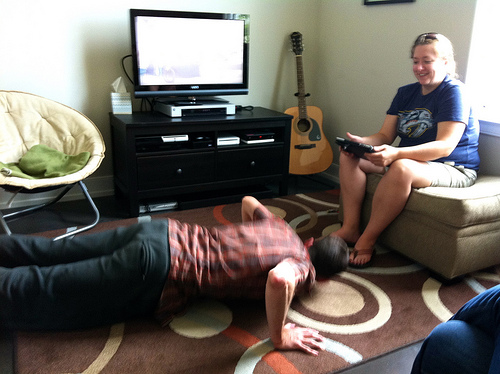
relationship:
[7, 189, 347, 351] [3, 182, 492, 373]
man on floor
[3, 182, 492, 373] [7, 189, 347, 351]
floor below man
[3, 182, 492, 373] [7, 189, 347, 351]
floor under man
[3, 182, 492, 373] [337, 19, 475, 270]
floor below woman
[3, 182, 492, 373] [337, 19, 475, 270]
floor under woman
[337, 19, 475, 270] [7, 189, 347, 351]
woman near man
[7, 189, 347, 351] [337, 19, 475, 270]
man near woman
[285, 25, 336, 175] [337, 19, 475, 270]
guitar near woman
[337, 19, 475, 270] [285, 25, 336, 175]
woman near guitar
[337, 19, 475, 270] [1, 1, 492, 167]
woman near wall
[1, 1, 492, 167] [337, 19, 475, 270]
wall near woman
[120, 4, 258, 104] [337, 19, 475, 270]
tv near woman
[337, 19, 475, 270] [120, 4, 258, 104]
woman near tv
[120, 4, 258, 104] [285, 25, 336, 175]
tv near guitar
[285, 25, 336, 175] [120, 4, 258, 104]
guitar near tv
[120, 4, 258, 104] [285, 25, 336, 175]
tv beside guitar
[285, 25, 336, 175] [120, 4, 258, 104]
guitar beside tv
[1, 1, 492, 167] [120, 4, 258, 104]
wall behind tv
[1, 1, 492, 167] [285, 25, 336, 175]
wall behind guitar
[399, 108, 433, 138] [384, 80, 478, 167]
symbol on shirt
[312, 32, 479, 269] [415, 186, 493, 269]
woman on sofa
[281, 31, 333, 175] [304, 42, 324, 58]
guitar in corner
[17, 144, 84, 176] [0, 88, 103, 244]
pillow in chair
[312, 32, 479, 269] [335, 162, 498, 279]
woman on sofa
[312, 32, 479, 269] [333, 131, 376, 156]
woman playing on tablet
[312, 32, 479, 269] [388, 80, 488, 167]
woman wearing shirt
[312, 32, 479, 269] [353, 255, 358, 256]
woman wearing thong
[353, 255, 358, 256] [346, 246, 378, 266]
thong on foot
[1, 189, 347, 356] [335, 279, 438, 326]
man on rug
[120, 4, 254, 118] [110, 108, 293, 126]
tv on counter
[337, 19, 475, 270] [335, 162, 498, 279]
woman on sofa